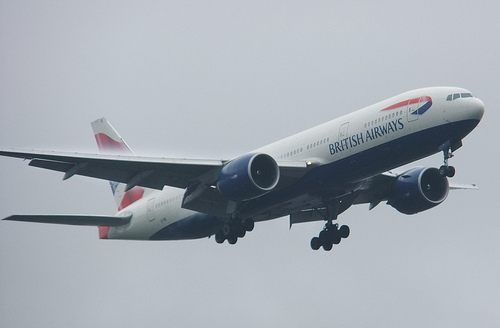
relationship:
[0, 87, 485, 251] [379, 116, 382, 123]
airplane has window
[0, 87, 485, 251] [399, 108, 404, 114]
airplane has window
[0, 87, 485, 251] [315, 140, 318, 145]
airplane has window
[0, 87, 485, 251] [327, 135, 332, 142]
airplane has window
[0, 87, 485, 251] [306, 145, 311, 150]
airplane has window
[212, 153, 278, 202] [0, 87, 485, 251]
engine on airplane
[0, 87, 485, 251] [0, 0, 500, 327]
airplane in air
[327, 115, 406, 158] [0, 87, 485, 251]
words on airplane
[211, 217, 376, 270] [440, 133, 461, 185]
wheels of landing gear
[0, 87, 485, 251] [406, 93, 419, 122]
airplane has door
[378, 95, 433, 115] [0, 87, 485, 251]
curve on airplane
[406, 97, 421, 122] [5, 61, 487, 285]
door on plane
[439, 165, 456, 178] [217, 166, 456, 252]
front wheel on landing gear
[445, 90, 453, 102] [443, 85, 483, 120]
window on cockpit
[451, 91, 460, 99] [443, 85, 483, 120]
window on cockpit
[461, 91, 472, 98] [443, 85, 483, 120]
window on cockpit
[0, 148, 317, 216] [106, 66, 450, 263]
wing on plane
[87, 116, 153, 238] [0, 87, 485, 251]
tail on airplane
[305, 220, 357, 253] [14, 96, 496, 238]
wheels on plane